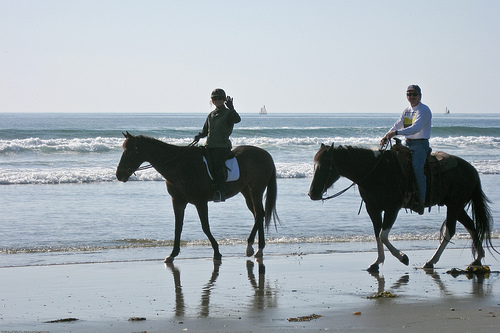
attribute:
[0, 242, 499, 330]
sand — wet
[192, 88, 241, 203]
woman — waving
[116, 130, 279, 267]
horse — large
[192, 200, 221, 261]
leg — long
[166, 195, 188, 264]
leg — long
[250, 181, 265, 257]
leg — long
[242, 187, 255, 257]
leg — long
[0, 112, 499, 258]
water — calm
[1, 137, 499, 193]
waves — swelling, white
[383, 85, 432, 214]
man — behind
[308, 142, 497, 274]
horse — large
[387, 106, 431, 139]
shirt — white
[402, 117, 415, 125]
design — yellow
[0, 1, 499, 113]
sky — pale blue, clear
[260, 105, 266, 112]
sails — white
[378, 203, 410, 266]
leg — folded, white